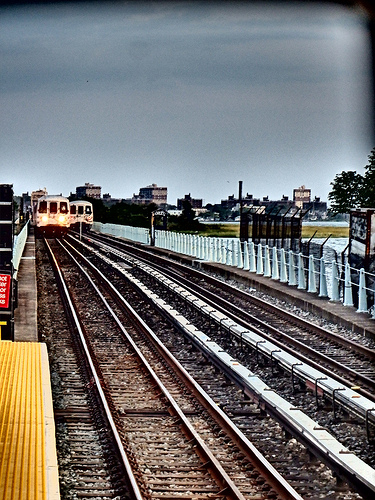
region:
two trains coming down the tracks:
[30, 192, 95, 240]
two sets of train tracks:
[38, 232, 374, 498]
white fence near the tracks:
[94, 220, 373, 317]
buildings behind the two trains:
[0, 180, 334, 218]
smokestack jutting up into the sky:
[236, 179, 244, 200]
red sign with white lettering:
[0, 272, 11, 307]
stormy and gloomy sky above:
[0, 2, 371, 205]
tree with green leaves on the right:
[325, 148, 373, 216]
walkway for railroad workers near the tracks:
[15, 227, 38, 340]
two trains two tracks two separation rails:
[7, 33, 368, 491]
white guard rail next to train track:
[94, 211, 368, 325]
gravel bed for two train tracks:
[32, 229, 364, 486]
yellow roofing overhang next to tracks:
[1, 338, 49, 497]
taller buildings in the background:
[66, 179, 327, 213]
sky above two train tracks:
[1, 1, 367, 196]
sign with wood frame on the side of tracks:
[347, 208, 373, 275]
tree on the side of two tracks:
[326, 147, 372, 219]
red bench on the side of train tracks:
[0, 274, 12, 309]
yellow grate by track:
[0, 336, 48, 494]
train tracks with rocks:
[37, 233, 249, 498]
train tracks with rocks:
[87, 213, 372, 431]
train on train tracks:
[33, 196, 72, 235]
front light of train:
[40, 215, 49, 223]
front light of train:
[60, 213, 69, 222]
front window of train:
[58, 200, 67, 215]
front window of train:
[47, 200, 58, 213]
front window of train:
[36, 200, 45, 213]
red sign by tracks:
[0, 273, 9, 305]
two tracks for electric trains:
[44, 233, 374, 498]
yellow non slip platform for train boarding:
[0, 337, 54, 498]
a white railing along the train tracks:
[87, 220, 374, 311]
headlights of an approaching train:
[40, 212, 66, 224]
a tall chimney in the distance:
[237, 179, 246, 199]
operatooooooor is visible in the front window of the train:
[58, 201, 67, 212]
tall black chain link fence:
[241, 207, 301, 252]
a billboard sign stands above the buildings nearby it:
[292, 184, 311, 203]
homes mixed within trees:
[224, 201, 309, 219]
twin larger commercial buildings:
[74, 182, 167, 206]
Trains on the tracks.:
[30, 188, 101, 245]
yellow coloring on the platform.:
[2, 339, 53, 498]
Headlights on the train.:
[38, 211, 66, 225]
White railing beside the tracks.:
[11, 216, 33, 275]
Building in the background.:
[134, 181, 169, 208]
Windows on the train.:
[34, 197, 69, 217]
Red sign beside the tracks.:
[0, 268, 14, 311]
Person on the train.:
[58, 200, 69, 216]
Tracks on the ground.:
[44, 232, 371, 498]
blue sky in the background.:
[0, 2, 371, 204]